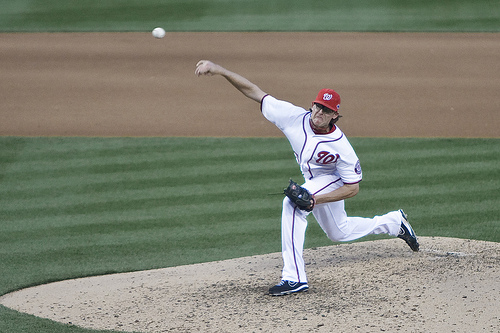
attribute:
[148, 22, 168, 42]
baseball — white, in air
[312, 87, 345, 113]
hat — red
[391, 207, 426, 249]
shoe — black, athletic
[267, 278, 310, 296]
shoe — black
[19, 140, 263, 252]
turf — green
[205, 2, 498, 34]
turf — green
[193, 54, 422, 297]
man — playing, pitching, throwing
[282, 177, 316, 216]
glove — black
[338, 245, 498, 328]
mound — tan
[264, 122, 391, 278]
uniform — white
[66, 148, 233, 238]
grass — manicured